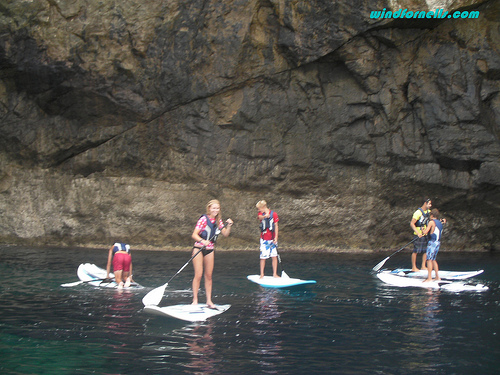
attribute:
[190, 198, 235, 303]
woman — standing, blonde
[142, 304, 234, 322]
board — white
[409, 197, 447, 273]
man — standing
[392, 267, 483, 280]
board — white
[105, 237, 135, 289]
person — kneeling, sitting, paddling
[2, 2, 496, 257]
cliff — rocky, brown, black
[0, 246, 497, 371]
water — calm, blue, grey, green, black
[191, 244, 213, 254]
swimsuit — black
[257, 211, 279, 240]
shirt — red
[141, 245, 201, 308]
oar — white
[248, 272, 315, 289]
board — blue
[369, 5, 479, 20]
website — written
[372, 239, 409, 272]
paddle — white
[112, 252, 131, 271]
shorts — red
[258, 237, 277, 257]
shorts — white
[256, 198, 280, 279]
boy — standing, blonde